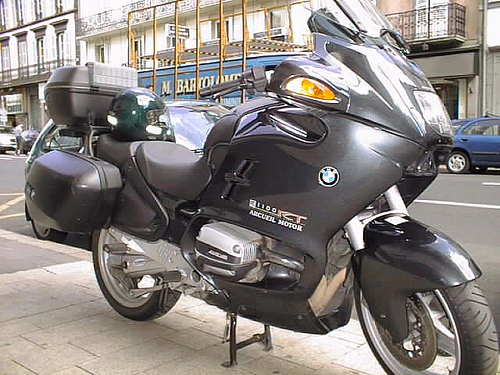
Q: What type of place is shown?
A: It is a road.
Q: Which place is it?
A: It is a road.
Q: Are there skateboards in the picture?
A: No, there are no skateboards.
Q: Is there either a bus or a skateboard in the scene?
A: No, there are no skateboards or buses.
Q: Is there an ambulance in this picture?
A: No, there are no ambulances.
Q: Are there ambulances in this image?
A: No, there are no ambulances.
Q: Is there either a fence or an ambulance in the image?
A: No, there are no ambulances or fences.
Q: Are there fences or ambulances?
A: No, there are no ambulances or fences.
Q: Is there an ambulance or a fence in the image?
A: No, there are no ambulances or fences.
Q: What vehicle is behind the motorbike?
A: The vehicle is a car.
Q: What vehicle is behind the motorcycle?
A: The vehicle is a car.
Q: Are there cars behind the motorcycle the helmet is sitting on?
A: Yes, there is a car behind the motorbike.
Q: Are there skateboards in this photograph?
A: No, there are no skateboards.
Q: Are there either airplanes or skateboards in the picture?
A: No, there are no skateboards or airplanes.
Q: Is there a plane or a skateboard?
A: No, there are no skateboards or airplanes.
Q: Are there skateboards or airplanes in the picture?
A: No, there are no skateboards or airplanes.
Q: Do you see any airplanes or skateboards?
A: No, there are no skateboards or airplanes.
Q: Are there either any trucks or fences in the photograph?
A: No, there are no fences or trucks.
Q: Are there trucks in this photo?
A: No, there are no trucks.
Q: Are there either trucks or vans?
A: No, there are no trucks or vans.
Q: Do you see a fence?
A: No, there are no fences.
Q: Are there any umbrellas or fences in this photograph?
A: No, there are no fences or umbrellas.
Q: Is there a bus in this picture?
A: No, there are no buses.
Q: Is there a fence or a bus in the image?
A: No, there are no buses or fences.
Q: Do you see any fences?
A: No, there are no fences.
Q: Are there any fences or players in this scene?
A: No, there are no fences or players.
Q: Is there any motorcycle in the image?
A: Yes, there is a motorcycle.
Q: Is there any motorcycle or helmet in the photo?
A: Yes, there is a motorcycle.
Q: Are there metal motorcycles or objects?
A: Yes, there is a metal motorcycle.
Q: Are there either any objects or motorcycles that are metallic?
A: Yes, the motorcycle is metallic.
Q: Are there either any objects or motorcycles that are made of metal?
A: Yes, the motorcycle is made of metal.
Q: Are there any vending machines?
A: No, there are no vending machines.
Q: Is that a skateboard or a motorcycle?
A: That is a motorcycle.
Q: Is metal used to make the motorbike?
A: Yes, the motorbike is made of metal.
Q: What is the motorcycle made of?
A: The motorcycle is made of metal.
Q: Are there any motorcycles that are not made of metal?
A: No, there is a motorcycle but it is made of metal.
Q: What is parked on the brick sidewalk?
A: The motorcycle is parked on the sidewalk.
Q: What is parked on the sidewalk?
A: The motorcycle is parked on the sidewalk.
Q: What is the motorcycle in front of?
A: The motorcycle is in front of the car.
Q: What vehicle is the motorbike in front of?
A: The motorbike is in front of the car.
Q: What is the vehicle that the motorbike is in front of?
A: The vehicle is a car.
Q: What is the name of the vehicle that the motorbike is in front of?
A: The vehicle is a car.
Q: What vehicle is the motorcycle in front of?
A: The motorbike is in front of the car.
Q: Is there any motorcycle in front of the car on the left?
A: Yes, there is a motorcycle in front of the car.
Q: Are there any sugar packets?
A: No, there are no sugar packets.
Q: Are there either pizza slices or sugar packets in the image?
A: No, there are no sugar packets or pizza slices.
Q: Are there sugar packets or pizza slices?
A: No, there are no sugar packets or pizza slices.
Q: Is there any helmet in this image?
A: Yes, there is a helmet.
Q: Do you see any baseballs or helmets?
A: Yes, there is a helmet.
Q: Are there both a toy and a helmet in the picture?
A: No, there is a helmet but no toys.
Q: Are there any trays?
A: No, there are no trays.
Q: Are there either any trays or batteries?
A: No, there are no trays or batteries.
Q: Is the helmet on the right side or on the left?
A: The helmet is on the left of the image.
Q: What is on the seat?
A: The helmet is on the seat.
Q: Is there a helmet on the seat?
A: Yes, there is a helmet on the seat.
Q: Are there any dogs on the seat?
A: No, there is a helmet on the seat.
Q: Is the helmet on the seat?
A: Yes, the helmet is on the seat.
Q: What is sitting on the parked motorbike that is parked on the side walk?
A: The helmet is sitting on the motorbike.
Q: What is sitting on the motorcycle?
A: The helmet is sitting on the motorbike.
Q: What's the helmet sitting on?
A: The helmet is sitting on the motorbike.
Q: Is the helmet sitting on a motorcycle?
A: Yes, the helmet is sitting on a motorcycle.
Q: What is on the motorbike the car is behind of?
A: The helmet is on the motorcycle.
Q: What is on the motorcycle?
A: The helmet is on the motorcycle.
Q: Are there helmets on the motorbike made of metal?
A: Yes, there is a helmet on the motorbike.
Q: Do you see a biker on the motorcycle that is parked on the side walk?
A: No, there is a helmet on the motorbike.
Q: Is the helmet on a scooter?
A: No, the helmet is on the motorbike.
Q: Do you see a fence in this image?
A: No, there are no fences.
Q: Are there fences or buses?
A: No, there are no fences or buses.